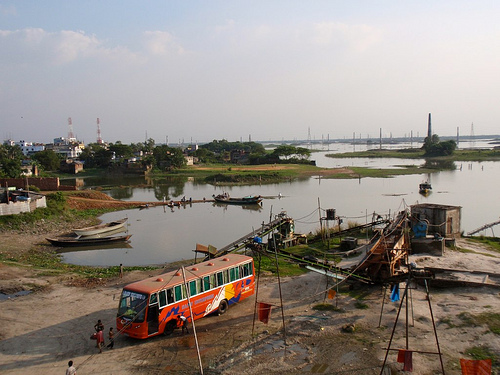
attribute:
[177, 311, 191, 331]
person — working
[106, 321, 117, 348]
person — standing, waiting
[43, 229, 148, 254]
boat — tied, docked, abandoned, wooden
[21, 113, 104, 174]
factory — in distance, large, white, block shaped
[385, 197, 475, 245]
shack — wooden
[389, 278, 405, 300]
flag — blue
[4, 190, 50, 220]
fence — white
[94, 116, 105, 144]
tower — red, radio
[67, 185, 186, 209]
ramp — dirt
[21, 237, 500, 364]
sand — wet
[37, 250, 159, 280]
grass — growing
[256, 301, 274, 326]
cloth — orange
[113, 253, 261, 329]
bus — parked, orange, red